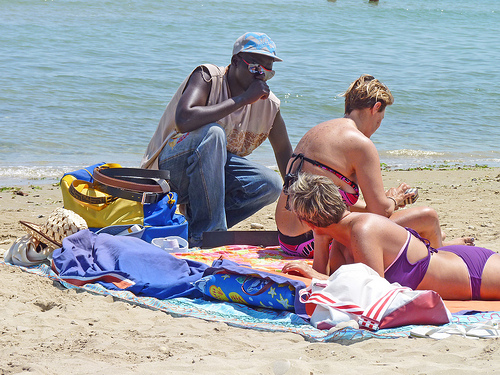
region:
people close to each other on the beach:
[20, 15, 475, 336]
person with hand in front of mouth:
[190, 30, 275, 155]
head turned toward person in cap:
[275, 165, 475, 305]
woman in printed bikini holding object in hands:
[260, 51, 425, 266]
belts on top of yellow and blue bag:
[50, 140, 192, 245]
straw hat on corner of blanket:
[11, 191, 101, 296]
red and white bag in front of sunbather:
[295, 241, 450, 336]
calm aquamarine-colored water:
[11, 20, 147, 140]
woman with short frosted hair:
[280, 166, 357, 227]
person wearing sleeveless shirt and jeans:
[137, 58, 275, 243]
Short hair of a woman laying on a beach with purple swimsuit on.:
[286, 170, 343, 228]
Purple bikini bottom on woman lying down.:
[437, 242, 493, 299]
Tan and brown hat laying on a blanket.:
[17, 209, 90, 251]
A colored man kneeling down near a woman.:
[140, 34, 295, 249]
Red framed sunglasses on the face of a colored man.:
[235, 51, 275, 83]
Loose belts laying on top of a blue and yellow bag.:
[70, 162, 170, 207]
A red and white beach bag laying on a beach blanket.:
[296, 262, 452, 333]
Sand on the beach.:
[37, 334, 91, 356]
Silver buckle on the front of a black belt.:
[138, 189, 160, 206]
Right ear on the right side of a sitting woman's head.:
[373, 98, 381, 117]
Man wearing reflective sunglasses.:
[221, 25, 281, 92]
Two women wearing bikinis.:
[280, 52, 499, 303]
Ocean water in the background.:
[18, 6, 491, 189]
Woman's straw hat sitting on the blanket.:
[9, 201, 133, 286]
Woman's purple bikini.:
[368, 209, 498, 302]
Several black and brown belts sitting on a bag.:
[70, 159, 175, 211]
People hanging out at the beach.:
[9, 7, 498, 353]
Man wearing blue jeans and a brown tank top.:
[140, 20, 296, 249]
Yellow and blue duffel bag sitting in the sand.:
[51, 150, 194, 248]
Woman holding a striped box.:
[379, 168, 428, 210]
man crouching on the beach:
[116, 3, 317, 273]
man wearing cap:
[227, 23, 296, 100]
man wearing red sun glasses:
[227, 40, 314, 102]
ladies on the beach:
[257, 59, 499, 331]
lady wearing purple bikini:
[274, 160, 499, 341]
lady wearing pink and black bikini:
[263, 72, 469, 286]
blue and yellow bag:
[42, 146, 194, 272]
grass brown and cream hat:
[12, 192, 99, 270]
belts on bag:
[63, 142, 193, 229]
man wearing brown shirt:
[109, 50, 316, 228]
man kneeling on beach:
[115, 19, 307, 255]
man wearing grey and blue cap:
[219, 11, 290, 111]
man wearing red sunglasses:
[225, 32, 289, 110]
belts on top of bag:
[55, 148, 197, 245]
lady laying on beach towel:
[280, 140, 499, 357]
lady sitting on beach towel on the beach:
[263, 49, 458, 304]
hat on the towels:
[12, 196, 110, 264]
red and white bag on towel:
[289, 264, 474, 356]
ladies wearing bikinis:
[251, 98, 492, 331]